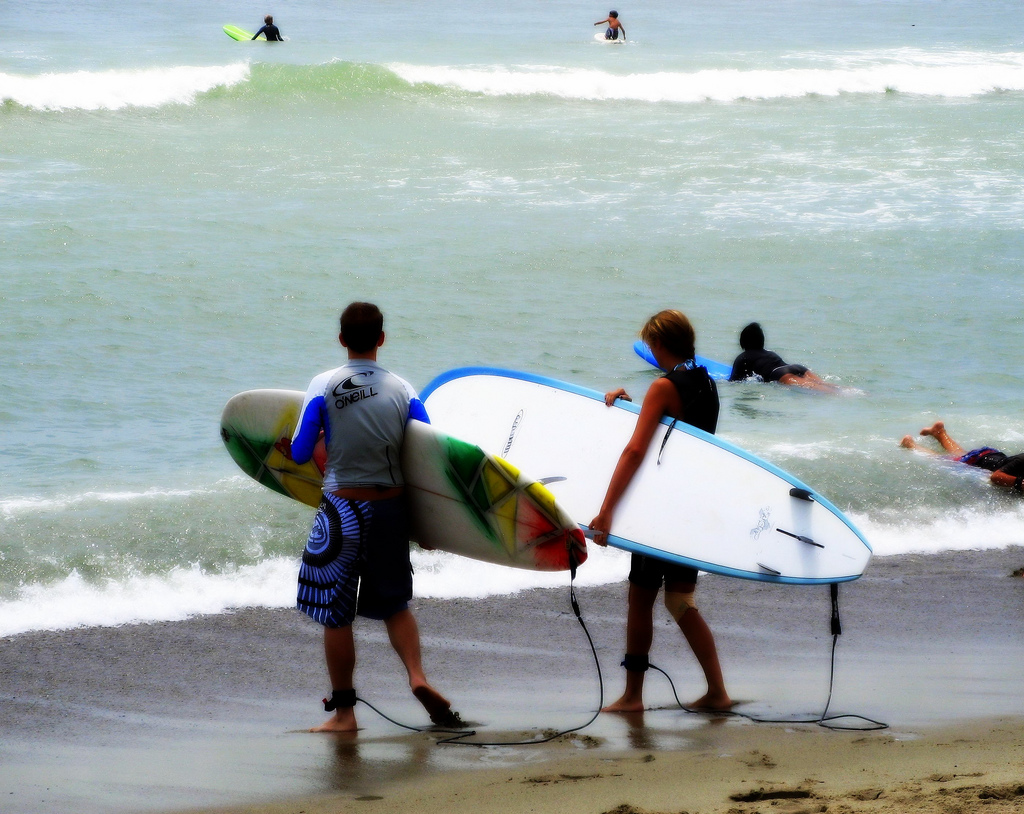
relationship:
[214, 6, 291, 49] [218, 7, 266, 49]
surfer paddling surfboard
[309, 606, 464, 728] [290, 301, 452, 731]
legs of boy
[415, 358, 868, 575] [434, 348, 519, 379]
surfboard with trim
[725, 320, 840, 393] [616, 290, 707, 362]
person with hair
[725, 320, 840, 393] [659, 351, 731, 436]
person with shirt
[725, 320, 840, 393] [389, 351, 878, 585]
person with surfboard